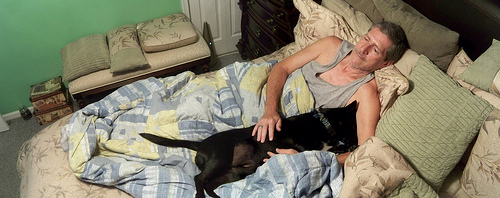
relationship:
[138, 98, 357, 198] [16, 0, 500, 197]
dog laying in bed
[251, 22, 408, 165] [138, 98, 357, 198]
man petting h dog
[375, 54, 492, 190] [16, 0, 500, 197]
pillow on bed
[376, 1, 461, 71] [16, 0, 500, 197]
pillow on bed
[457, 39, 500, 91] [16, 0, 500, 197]
pillow on bed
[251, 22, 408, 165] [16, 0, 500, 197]
man inside bed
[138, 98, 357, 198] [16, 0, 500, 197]
dog on top of bed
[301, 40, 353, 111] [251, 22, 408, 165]
tank top on man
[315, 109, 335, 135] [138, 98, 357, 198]
collar on dog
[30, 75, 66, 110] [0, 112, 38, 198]
box on floor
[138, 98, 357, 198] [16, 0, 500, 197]
dog on bed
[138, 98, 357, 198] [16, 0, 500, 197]
dog laying on bed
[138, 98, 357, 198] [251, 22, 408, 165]
dog laying on man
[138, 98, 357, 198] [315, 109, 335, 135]
dog wearing collar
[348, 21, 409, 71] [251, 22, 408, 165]
head of man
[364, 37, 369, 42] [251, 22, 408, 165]
eye on man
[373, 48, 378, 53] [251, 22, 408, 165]
eye on man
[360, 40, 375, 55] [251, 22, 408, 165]
nose on man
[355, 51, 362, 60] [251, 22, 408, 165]
mouth of man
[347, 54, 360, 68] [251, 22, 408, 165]
chin on man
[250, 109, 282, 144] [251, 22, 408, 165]
hand of man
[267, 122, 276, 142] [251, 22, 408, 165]
finger of man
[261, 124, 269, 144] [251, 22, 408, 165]
finger of man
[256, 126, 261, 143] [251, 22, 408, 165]
finger of man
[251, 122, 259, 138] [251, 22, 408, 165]
finger of man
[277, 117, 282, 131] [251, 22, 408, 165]
finger of man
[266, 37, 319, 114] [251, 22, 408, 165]
arm of man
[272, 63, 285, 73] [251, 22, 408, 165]
elbow of man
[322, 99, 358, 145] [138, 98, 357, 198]
head of dog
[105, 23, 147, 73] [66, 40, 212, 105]
cushion on chair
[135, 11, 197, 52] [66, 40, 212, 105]
cushion on chair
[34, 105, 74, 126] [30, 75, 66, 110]
box under box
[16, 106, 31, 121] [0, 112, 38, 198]
jar on floor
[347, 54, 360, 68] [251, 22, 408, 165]
chin of man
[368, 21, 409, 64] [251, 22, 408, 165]
hair of man